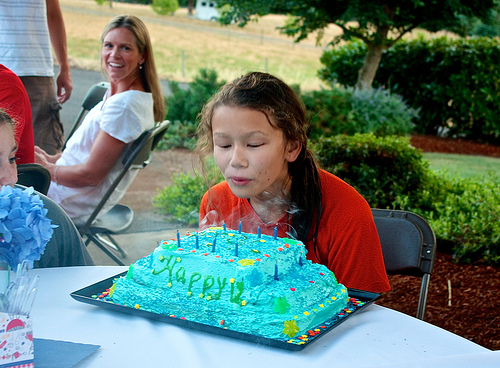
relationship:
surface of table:
[2, 263, 496, 364] [16, 264, 491, 366]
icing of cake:
[112, 223, 348, 339] [97, 202, 353, 367]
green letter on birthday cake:
[149, 248, 171, 290] [108, 221, 350, 337]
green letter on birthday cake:
[171, 264, 179, 286] [108, 221, 350, 337]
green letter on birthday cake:
[184, 268, 199, 299] [108, 221, 350, 337]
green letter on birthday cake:
[199, 274, 215, 300] [108, 221, 350, 337]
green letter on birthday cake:
[209, 274, 230, 306] [108, 221, 350, 337]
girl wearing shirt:
[21, 14, 163, 228] [46, 88, 153, 225]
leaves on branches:
[147, 1, 497, 266] [333, 22, 413, 51]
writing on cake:
[152, 251, 246, 306] [116, 207, 346, 353]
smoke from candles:
[191, 188, 304, 239] [175, 217, 305, 281]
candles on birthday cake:
[170, 227, 242, 259] [108, 217, 357, 338]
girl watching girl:
[21, 14, 163, 228] [194, 67, 394, 300]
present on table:
[2, 302, 40, 366] [107, 348, 476, 365]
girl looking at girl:
[1, 109, 98, 271] [21, 14, 163, 228]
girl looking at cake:
[1, 109, 98, 271] [106, 215, 354, 341]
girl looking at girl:
[1, 109, 98, 271] [194, 67, 394, 300]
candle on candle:
[176, 231, 183, 247] [193, 230, 200, 247]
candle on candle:
[176, 231, 183, 247] [210, 232, 217, 251]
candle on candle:
[176, 231, 183, 247] [232, 242, 239, 255]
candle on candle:
[176, 231, 183, 247] [273, 260, 280, 278]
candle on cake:
[176, 231, 183, 247] [108, 226, 350, 339]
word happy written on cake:
[152, 255, 246, 303] [113, 259, 330, 350]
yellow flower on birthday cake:
[279, 315, 302, 338] [108, 221, 350, 337]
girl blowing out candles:
[194, 67, 394, 300] [171, 217, 296, 278]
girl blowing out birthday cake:
[194, 67, 394, 300] [107, 221, 351, 346]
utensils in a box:
[7, 262, 41, 327] [3, 326, 37, 362]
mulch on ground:
[380, 253, 499, 350] [4, 110, 498, 348]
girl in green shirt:
[1, 109, 97, 271] [9, 180, 94, 268]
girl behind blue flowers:
[1, 109, 97, 271] [1, 182, 58, 269]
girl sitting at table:
[1, 109, 97, 271] [16, 264, 491, 366]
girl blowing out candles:
[194, 67, 394, 300] [156, 213, 306, 285]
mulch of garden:
[380, 253, 499, 350] [358, 113, 483, 251]